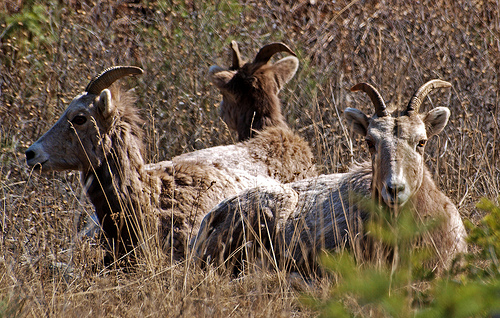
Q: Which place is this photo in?
A: It is at the field.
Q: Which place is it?
A: It is a field.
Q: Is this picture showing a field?
A: Yes, it is showing a field.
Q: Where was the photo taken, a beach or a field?
A: It was taken at a field.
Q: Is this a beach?
A: No, it is a field.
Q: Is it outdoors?
A: Yes, it is outdoors.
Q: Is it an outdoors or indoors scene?
A: It is outdoors.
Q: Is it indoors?
A: No, it is outdoors.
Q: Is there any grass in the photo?
A: Yes, there is grass.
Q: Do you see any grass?
A: Yes, there is grass.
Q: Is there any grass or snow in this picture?
A: Yes, there is grass.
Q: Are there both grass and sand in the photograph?
A: No, there is grass but no sand.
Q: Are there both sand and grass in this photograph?
A: No, there is grass but no sand.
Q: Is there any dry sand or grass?
A: Yes, there is dry grass.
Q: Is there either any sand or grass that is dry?
A: Yes, the grass is dry.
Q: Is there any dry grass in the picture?
A: Yes, there is dry grass.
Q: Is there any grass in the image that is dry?
A: Yes, there is grass that is dry.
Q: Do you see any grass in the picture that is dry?
A: Yes, there is grass that is dry.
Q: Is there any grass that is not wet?
A: Yes, there is dry grass.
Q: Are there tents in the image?
A: No, there are no tents.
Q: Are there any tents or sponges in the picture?
A: No, there are no tents or sponges.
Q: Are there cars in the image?
A: No, there are no cars.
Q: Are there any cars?
A: No, there are no cars.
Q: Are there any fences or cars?
A: No, there are no cars or fences.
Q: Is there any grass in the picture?
A: Yes, there is grass.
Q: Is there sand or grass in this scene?
A: Yes, there is grass.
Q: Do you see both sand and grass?
A: No, there is grass but no sand.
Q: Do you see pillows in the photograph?
A: No, there are no pillows.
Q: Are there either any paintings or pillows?
A: No, there are no pillows or paintings.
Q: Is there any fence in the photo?
A: No, there are no fences.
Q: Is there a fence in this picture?
A: No, there are no fences.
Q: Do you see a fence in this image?
A: No, there are no fences.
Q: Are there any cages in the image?
A: No, there are no cages.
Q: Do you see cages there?
A: No, there are no cages.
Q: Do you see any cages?
A: No, there are no cages.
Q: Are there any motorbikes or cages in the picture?
A: No, there are no cages or motorbikes.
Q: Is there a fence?
A: No, there are no fences.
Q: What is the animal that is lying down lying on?
A: The animal is lying on the ground.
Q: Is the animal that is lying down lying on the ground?
A: Yes, the animal is lying on the ground.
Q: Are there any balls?
A: No, there are no balls.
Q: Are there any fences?
A: No, there are no fences.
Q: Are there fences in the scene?
A: No, there are no fences.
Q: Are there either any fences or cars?
A: No, there are no fences or cars.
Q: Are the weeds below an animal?
A: Yes, the weeds are below an animal.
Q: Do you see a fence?
A: No, there are no fences.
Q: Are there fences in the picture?
A: No, there are no fences.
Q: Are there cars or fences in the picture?
A: No, there are no fences or cars.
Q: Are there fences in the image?
A: No, there are no fences.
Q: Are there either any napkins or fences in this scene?
A: No, there are no fences or napkins.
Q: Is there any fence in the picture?
A: No, there are no fences.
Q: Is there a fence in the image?
A: No, there are no fences.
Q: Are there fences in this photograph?
A: No, there are no fences.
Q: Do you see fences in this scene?
A: No, there are no fences.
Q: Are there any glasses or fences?
A: No, there are no fences or glasses.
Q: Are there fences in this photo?
A: No, there are no fences.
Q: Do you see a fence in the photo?
A: No, there are no fences.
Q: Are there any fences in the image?
A: No, there are no fences.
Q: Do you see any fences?
A: No, there are no fences.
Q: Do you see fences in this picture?
A: No, there are no fences.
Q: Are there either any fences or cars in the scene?
A: No, there are no fences or cars.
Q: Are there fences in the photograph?
A: No, there are no fences.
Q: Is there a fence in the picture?
A: No, there are no fences.